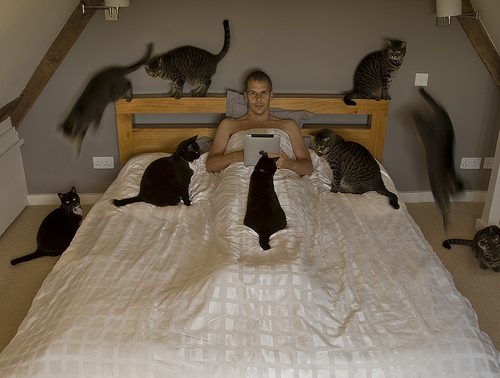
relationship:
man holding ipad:
[205, 70, 313, 179] [244, 131, 283, 168]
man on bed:
[205, 70, 313, 179] [0, 91, 499, 375]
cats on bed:
[112, 29, 407, 252] [0, 91, 499, 375]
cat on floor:
[9, 186, 83, 267] [1, 203, 499, 351]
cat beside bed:
[9, 186, 83, 267] [0, 91, 499, 375]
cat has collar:
[240, 153, 290, 253] [255, 164, 268, 176]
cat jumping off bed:
[413, 83, 471, 232] [0, 91, 499, 375]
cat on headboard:
[342, 35, 410, 106] [114, 95, 391, 167]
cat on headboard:
[146, 18, 233, 99] [114, 95, 391, 167]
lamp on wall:
[434, 0, 481, 27] [17, 0, 499, 206]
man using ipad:
[205, 70, 313, 179] [244, 131, 283, 168]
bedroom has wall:
[5, 3, 496, 377] [17, 0, 499, 206]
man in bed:
[205, 70, 313, 179] [0, 91, 499, 375]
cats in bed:
[112, 29, 407, 252] [0, 91, 499, 375]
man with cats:
[205, 70, 313, 179] [112, 29, 407, 252]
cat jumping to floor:
[413, 83, 471, 232] [1, 203, 499, 351]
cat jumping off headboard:
[53, 32, 154, 156] [114, 95, 391, 167]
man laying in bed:
[205, 70, 313, 179] [0, 91, 499, 375]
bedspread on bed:
[3, 153, 498, 377] [0, 91, 499, 375]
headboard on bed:
[114, 95, 391, 167] [0, 91, 499, 375]